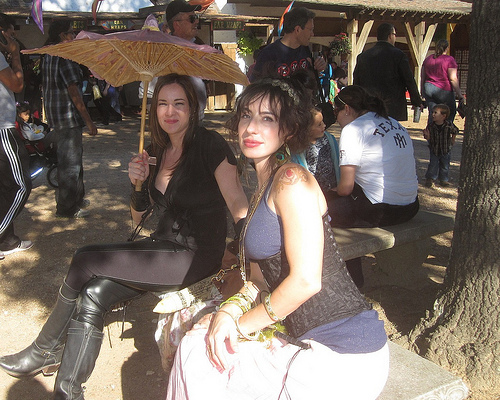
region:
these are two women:
[134, 92, 301, 273]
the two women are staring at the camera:
[125, 71, 308, 272]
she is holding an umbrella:
[119, 35, 195, 78]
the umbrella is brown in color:
[111, 35, 179, 70]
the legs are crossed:
[48, 241, 178, 311]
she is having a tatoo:
[278, 163, 309, 191]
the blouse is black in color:
[180, 177, 216, 230]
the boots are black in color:
[20, 323, 94, 379]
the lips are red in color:
[242, 137, 262, 149]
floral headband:
[251, 75, 301, 92]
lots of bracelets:
[219, 288, 259, 323]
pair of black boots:
[0, 279, 106, 397]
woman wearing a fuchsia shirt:
[419, 38, 461, 103]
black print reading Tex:
[370, 117, 396, 135]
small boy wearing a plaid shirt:
[422, 100, 457, 186]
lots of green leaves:
[236, 30, 261, 52]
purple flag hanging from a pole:
[22, 0, 42, 37]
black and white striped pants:
[1, 127, 31, 229]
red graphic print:
[271, 55, 316, 76]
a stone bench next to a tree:
[309, 205, 471, 265]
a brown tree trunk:
[402, 0, 496, 392]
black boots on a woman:
[4, 284, 104, 394]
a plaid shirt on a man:
[27, 43, 88, 135]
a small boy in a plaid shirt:
[418, 100, 462, 186]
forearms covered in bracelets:
[210, 271, 305, 358]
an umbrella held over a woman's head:
[25, 11, 241, 200]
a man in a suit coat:
[351, 19, 427, 128]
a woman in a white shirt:
[322, 87, 436, 236]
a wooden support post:
[402, 15, 447, 121]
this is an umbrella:
[45, 30, 230, 69]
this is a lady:
[204, 86, 313, 384]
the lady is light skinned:
[290, 213, 322, 253]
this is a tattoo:
[276, 162, 313, 183]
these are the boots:
[44, 325, 70, 398]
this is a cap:
[166, 1, 198, 10]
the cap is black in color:
[171, 1, 180, 12]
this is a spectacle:
[188, 12, 197, 21]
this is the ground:
[16, 264, 46, 296]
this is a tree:
[460, 32, 490, 309]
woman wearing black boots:
[2, 271, 122, 397]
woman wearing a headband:
[190, 63, 314, 130]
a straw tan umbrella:
[15, 2, 235, 137]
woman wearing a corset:
[225, 199, 365, 321]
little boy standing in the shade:
[402, 87, 457, 187]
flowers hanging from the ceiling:
[299, 17, 369, 79]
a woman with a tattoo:
[248, 159, 322, 203]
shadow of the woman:
[86, 272, 160, 389]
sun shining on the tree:
[411, 39, 498, 354]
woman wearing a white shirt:
[310, 82, 420, 204]